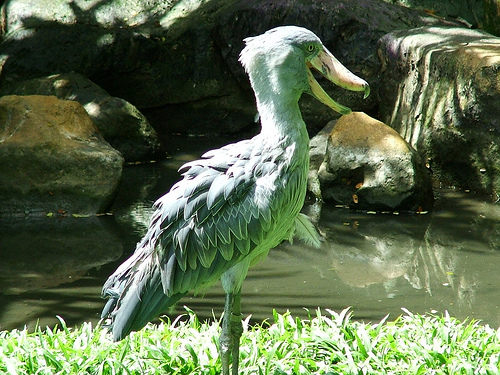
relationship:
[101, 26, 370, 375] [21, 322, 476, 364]
animal standing on grass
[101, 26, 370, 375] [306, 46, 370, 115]
animal has beak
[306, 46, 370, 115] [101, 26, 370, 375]
beak on animal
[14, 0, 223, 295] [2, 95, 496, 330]
pond shadow on pond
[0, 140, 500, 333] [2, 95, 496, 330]
pond shadow on pond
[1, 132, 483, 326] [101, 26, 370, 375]
pond next to animal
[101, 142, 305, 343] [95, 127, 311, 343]
feathers on body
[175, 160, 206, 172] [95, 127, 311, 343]
feathers on body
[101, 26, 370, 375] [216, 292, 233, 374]
animal with leg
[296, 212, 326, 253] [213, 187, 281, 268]
feather near abdomen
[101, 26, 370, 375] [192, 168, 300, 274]
animal has feathers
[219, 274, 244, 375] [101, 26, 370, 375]
leg on animal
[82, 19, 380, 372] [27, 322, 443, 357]
animal in grass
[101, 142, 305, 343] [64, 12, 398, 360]
feathers on bird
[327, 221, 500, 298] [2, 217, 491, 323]
reflection on water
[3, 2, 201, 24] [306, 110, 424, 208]
sunlight on boulder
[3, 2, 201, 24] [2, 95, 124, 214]
sunlight on rock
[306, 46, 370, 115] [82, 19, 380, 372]
beak on animal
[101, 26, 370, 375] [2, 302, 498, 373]
animal on grass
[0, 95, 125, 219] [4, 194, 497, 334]
rock lining pond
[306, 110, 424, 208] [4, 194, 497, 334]
boulder lining pond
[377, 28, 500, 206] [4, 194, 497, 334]
rock lining pond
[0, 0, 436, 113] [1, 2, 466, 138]
shadow on rock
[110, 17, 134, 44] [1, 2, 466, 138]
shadow on rock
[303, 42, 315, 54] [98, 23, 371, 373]
birds eye of gray bird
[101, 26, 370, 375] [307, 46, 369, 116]
animal with beak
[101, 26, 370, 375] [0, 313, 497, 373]
animal standing in grass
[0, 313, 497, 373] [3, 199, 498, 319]
grass growing on edge of water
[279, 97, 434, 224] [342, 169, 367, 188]
boulder with holes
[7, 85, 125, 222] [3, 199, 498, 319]
rock next to water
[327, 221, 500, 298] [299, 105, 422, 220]
reflection of rock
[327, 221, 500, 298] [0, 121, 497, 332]
reflection in water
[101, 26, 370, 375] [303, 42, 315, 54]
animal has birds eye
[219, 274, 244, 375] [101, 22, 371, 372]
leg of birds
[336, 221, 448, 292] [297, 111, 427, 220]
reflection of rock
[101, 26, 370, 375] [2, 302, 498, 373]
animal standing in grass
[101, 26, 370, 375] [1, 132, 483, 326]
animal near pond